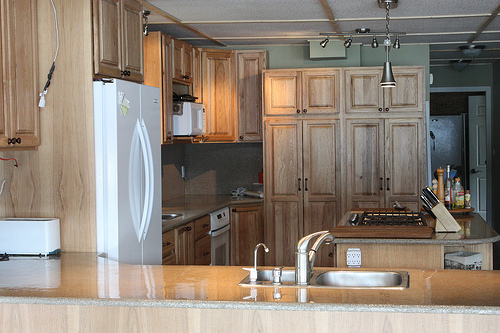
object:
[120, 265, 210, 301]
reflection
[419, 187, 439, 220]
knife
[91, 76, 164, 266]
fridge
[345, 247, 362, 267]
outlets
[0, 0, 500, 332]
kitchen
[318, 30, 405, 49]
lights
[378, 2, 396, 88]
lights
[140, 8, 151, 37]
lights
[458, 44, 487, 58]
lights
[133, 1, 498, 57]
ceiling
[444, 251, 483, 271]
can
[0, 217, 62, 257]
toaster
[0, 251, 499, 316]
counter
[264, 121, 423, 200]
cupboards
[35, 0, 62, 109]
cord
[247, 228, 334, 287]
faucet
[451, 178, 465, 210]
condiment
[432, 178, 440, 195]
condiment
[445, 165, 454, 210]
condiment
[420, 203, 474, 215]
tray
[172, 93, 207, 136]
microwave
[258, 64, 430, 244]
cabinets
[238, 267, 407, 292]
sink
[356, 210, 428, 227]
counter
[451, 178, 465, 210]
bottles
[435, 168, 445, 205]
peppermill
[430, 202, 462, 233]
knifeblock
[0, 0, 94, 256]
wall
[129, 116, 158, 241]
handles